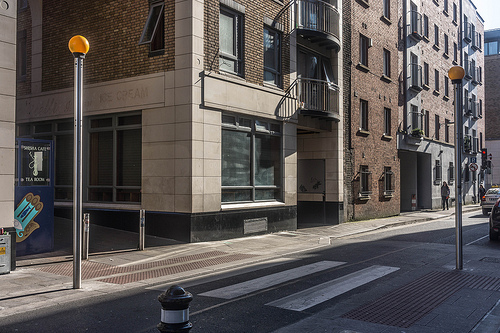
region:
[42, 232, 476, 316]
a pedestrian cross walk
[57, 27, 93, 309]
a large metal pole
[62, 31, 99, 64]
a yellow ball on a pole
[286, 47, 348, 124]
an apartment balcony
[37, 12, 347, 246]
a tan and brick building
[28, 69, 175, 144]
an ice cream store sign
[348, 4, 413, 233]
a thing brick building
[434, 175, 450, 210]
a woman walking on the side walk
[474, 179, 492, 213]
a white bar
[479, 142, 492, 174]
a red traffic light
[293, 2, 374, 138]
balconies on a building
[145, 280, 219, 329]
black and white metal post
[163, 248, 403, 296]
pedestrian cross walk with white lines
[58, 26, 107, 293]
metal pole topped by a yellow ball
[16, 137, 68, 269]
blue door to a tea room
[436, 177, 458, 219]
person walking down the street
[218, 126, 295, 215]
double windows in a stone building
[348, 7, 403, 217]
multi-storied brick building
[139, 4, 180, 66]
open window in a brick building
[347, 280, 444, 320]
rumble strips on the sidewalk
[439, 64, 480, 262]
street light has yellow globe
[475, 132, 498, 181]
the street light is red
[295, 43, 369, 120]
balcony on the buidling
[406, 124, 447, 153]
flowers outside the window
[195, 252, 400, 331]
white lines on the road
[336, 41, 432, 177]
building is made from bricks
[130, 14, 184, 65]
the window is open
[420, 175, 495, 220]
people walking on the sidewalk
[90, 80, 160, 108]
ice cream written on the building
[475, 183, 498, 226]
car stopped at the street light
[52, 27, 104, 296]
a tall street pole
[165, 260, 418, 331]
two white street lines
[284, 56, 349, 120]
balcony above the street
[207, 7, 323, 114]
windows on the building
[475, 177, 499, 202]
vehicle on the road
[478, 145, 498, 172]
red traffic light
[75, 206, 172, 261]
two short poles on the road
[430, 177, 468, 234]
a person walking on the sidewalk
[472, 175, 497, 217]
a vehicles with brake lights on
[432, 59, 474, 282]
a street light on the sidewalk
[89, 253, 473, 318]
a pedestrian crosswalk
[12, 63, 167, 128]
a sign for an ice cream store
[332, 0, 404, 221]
a brick apartment building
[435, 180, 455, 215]
a woman walking on the sidewalk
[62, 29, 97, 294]
a metal pole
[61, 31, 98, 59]
a yellow sphere on a pole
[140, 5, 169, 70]
an open window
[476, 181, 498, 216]
a white car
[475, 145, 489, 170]
a traffic light on red